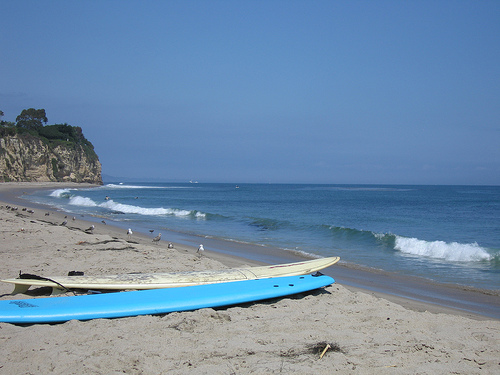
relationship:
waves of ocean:
[384, 235, 495, 265] [5, 180, 499, 287]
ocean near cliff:
[5, 180, 499, 287] [0, 106, 105, 188]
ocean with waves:
[5, 180, 499, 287] [384, 235, 495, 265]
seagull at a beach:
[195, 243, 206, 254] [2, 2, 499, 373]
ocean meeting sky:
[5, 180, 499, 287] [1, 1, 499, 184]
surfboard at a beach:
[2, 269, 337, 327] [2, 2, 499, 373]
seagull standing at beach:
[195, 243, 206, 254] [2, 2, 499, 373]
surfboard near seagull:
[2, 269, 337, 327] [195, 243, 206, 254]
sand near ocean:
[0, 178, 497, 375] [5, 180, 499, 287]